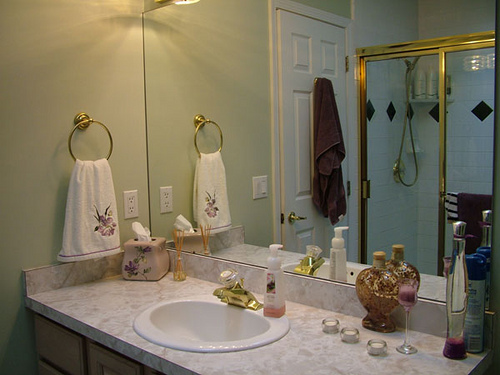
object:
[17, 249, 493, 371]
bathroom counter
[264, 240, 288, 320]
soap bottle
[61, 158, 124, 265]
towel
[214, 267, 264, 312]
brass faucet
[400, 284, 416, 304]
candle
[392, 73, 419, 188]
shower hose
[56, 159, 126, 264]
hand towel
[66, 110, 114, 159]
bronze holder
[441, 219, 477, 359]
long bottle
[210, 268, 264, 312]
faucet fixture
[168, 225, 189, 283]
aroma oil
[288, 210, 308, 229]
door handle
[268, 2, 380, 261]
white door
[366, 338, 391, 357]
small candles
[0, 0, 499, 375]
bathroom photo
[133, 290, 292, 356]
white sink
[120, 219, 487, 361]
items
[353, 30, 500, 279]
gold shower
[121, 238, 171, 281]
dispenser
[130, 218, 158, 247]
paper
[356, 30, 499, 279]
frame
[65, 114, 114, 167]
towel rack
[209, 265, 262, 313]
bathroom faucet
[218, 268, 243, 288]
handle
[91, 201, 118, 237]
flower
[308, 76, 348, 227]
towel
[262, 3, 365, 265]
door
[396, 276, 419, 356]
glass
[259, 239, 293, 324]
bottle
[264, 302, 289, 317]
soap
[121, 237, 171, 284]
kleenex box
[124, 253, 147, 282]
flower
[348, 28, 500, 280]
shower door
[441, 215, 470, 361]
bottle